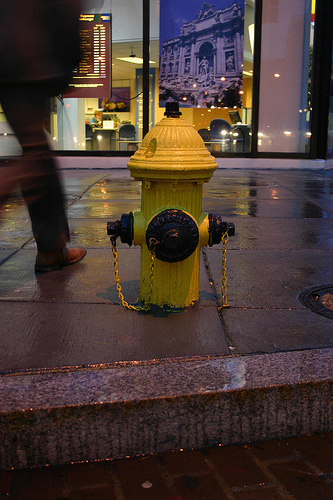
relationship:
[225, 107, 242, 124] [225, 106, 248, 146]
lap top at desk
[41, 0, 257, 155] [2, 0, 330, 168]
window of building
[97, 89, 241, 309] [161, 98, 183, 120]
fire hydrant has cap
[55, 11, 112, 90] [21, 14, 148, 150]
sign in window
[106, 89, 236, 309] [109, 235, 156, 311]
fire hydrant has chain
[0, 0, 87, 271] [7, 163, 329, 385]
man walking on sidewalk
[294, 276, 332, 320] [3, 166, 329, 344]
man hole on sidewalk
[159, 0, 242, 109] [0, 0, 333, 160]
picture in window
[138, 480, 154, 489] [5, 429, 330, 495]
gum on street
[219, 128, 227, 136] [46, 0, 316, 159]
headlights reflected in window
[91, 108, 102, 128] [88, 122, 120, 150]
person sitting in a desk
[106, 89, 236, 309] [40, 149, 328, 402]
fire hydrant on sidewalk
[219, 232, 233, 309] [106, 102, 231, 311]
chain on fire hydrant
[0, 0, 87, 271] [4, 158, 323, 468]
man on sidewalk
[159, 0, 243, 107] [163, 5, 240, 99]
banner on building monument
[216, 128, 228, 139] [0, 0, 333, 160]
light reflection on window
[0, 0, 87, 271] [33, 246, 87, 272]
man wearing shoe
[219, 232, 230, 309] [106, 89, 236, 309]
chain on fire hydrant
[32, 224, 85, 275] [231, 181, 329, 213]
boot on sidewalk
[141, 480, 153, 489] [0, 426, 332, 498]
gum stuck to bricks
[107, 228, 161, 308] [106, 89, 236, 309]
chain on fire hydrant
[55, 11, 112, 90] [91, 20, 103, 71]
sign on business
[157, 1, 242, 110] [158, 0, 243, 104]
poster of building monument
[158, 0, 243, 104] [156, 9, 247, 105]
building monument in rome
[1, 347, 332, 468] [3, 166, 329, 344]
curb near a sidewalk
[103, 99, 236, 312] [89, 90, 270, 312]
side of fire hydrant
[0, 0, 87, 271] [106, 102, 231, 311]
man walking near fire hydrant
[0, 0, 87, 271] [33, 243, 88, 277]
man wearing boot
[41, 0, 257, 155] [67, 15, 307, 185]
window on a store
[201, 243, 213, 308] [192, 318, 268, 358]
crack in sidewalk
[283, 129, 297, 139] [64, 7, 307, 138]
light reflecting in window